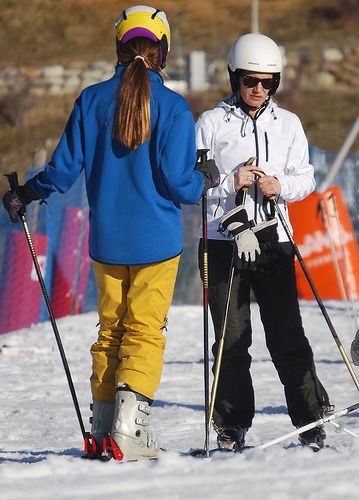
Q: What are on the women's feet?
A: Skis.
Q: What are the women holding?
A: Ski poles.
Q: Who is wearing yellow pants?
A: Nearest woman.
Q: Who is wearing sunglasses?
A: Woman in white.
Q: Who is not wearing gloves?
A: Woman in white.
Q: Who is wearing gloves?
A: Woman in blue.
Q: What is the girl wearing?
A: Sweater.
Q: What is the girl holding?
A: Poles.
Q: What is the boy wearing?
A: Jacket.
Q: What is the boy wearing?
A: Pant.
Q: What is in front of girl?
A: Poles.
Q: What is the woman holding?
A: Poles.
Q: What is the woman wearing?
A: Yellow pant.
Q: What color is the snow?
A: White.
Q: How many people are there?
A: Two.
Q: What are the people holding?
A: Ski poles.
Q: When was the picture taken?
A: Daytime.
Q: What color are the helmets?
A: White, yellow, and purple.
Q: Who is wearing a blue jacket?
A: The woman on the left.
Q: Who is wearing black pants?
A: The woman on the right.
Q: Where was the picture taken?
A: At a skiing competition.